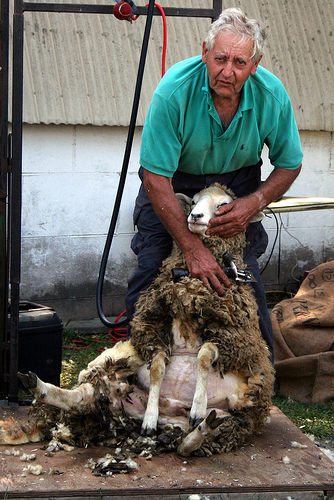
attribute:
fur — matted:
[131, 235, 262, 380]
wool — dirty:
[133, 313, 318, 361]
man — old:
[104, 13, 317, 257]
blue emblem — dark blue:
[239, 142, 246, 152]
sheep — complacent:
[107, 176, 301, 426]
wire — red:
[133, 1, 168, 77]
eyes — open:
[212, 49, 247, 67]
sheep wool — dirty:
[20, 465, 41, 477]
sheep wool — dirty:
[129, 437, 153, 455]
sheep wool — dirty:
[41, 440, 74, 451]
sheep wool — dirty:
[87, 453, 136, 475]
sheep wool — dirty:
[288, 438, 301, 445]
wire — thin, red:
[153, 3, 166, 76]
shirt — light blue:
[135, 51, 306, 179]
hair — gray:
[200, 3, 267, 60]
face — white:
[186, 194, 228, 231]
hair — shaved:
[0, 417, 145, 479]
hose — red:
[129, 4, 169, 82]